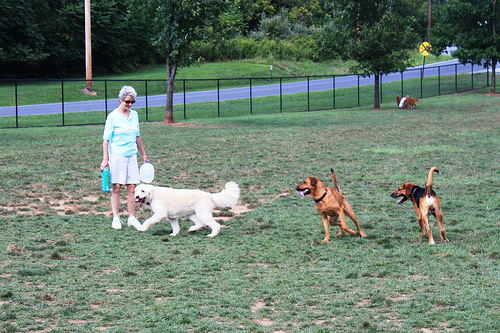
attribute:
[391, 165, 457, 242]
dog — brown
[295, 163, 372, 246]
dog — is brown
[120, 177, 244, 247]
dog — is brown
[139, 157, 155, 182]
bottle — white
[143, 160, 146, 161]
top — blue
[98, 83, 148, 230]
woman — carrying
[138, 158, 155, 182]
jug — water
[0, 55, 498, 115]
road — tarmacked, blue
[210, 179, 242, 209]
tail — bushy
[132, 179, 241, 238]
dog — walking, white, standing, playing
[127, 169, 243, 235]
dog — playing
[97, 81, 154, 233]
woman — wearing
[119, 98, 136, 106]
sunglasses — black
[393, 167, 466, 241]
dog — brown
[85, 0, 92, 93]
pole — telephone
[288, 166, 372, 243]
dogs — medium, brown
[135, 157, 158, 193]
water — gallon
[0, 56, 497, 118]
street — beside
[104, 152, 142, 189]
shorts — white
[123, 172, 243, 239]
dog — fluffy, white, big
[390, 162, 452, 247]
brown dog — playing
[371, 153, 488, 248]
dog — black, brown, medium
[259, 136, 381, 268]
dog — running, brown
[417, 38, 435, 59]
sign — yellow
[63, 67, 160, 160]
shirt — light blue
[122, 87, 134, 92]
hair — light gray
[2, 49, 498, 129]
fence — chain link, black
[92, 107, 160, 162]
shirt — blue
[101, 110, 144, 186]
clothing — light colored